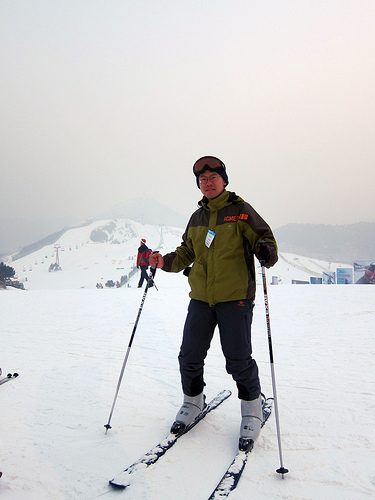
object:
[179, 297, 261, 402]
pants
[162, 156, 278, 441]
man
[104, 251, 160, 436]
poles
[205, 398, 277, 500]
skis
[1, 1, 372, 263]
sky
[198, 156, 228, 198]
head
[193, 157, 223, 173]
goggles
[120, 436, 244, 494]
snow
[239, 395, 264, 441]
boots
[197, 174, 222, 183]
glasses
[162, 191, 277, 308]
jacket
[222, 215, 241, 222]
acme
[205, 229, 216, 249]
tag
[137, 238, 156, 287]
person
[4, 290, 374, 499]
ground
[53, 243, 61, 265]
lift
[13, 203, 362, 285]
distance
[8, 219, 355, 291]
mountain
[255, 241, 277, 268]
gloves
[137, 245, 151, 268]
jacket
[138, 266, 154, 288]
pants